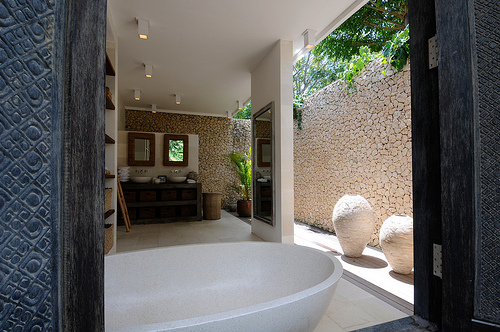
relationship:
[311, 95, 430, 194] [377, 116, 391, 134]
wall made of stone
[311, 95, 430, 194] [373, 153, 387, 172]
wall made of stone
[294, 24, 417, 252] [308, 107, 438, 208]
wall has stones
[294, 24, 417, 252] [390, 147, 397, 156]
wall has stone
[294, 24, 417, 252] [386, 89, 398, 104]
wall has stone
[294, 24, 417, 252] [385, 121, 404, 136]
wall has stone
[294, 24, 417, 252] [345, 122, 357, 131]
wall has stone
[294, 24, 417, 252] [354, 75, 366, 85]
wall has stone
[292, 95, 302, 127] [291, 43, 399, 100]
plant over edge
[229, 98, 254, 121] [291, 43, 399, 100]
plant over edge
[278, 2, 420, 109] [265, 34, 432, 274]
hedge under tree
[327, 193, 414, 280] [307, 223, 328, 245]
statues on ground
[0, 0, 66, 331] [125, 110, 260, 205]
pattern on wall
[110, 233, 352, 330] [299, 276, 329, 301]
bathtub has rim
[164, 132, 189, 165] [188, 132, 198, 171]
mirror on wall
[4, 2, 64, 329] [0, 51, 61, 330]
pattern on wall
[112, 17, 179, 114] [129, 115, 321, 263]
lights on wall